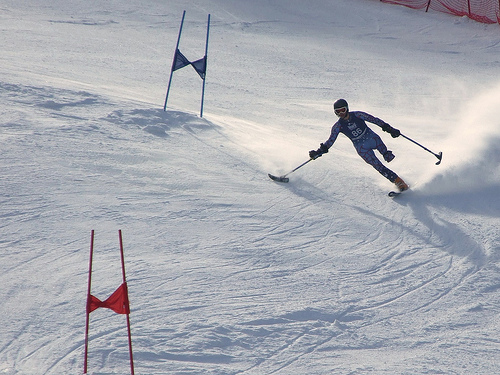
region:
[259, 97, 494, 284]
the man is skiing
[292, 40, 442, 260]
the man is skiing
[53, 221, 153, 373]
Red poles with flag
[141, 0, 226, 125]
Blue poles with flag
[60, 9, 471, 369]
Downhill skiing race course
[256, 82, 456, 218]
Skier missing part of a leg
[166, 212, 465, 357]
Ski tracks in the snow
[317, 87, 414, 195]
Skier wearing a helmet and goggles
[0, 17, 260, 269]
Snow on a hill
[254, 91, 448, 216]
Skier with one ski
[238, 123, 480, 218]
Special ski poles with small skies on the ends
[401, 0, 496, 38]
Orange mesh fence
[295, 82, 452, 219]
a person with half a leg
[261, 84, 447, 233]
a person skiing down a hill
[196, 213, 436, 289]
tracks in the snow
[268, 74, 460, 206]
a person holding ski poles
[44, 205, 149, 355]
a red flag on two poles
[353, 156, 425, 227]
a person's foot on a ski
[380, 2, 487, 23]
a red safety fence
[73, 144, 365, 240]
the ground covered with snow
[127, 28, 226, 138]
a blue flag on two poles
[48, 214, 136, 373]
red flags with white snow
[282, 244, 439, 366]
ski tracks in the snow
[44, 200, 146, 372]
two poles with flag in between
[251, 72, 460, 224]
a person skiing with 2 poles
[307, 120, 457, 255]
person skiing with one foot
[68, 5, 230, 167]
blue flag in snow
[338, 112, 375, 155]
white number 86 on shirt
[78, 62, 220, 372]
red and blue flags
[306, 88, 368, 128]
a white ski mask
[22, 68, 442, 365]
person skiing in a competition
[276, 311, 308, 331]
the snow is clear white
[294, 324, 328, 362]
the snow is clear white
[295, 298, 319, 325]
the snow is clear white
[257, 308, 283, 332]
the snow is clear white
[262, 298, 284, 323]
the snow is clear white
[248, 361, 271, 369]
the snow is clear white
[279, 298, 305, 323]
the snow is clear white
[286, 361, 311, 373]
the snow is clear white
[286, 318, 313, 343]
the snow is clear white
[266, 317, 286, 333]
the snow is clear white